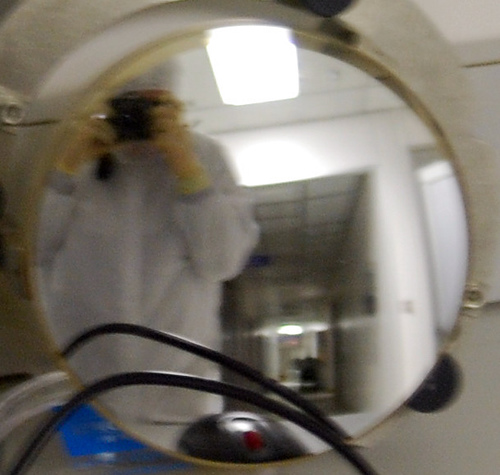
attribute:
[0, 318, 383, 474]
wires — thick, black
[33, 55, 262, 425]
person — scientist, working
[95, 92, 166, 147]
camera — black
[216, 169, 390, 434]
hallway — long, white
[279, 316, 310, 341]
light — bright, white, fluorescent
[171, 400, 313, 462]
mouse — grey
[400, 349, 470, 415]
circle — black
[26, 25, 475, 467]
mirror — round, large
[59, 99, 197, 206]
gloves — yellow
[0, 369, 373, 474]
wire — black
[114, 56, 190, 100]
cap — white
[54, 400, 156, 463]
item — blue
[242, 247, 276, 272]
sign — blue